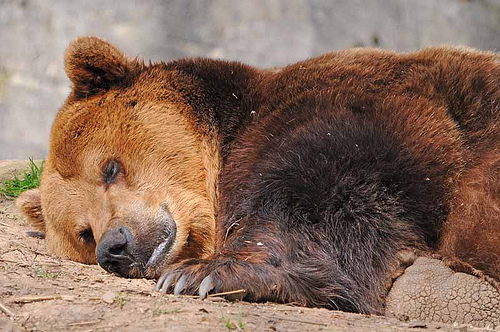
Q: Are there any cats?
A: No, there are no cats.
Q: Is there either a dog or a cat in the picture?
A: No, there are no cats or dogs.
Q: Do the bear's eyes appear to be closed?
A: Yes, the eyes are closed.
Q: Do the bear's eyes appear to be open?
A: No, the eyes are closed.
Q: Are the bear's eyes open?
A: No, the eyes are closed.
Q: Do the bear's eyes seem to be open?
A: No, the eyes are closed.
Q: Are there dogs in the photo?
A: No, there are no dogs.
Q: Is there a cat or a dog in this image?
A: No, there are no dogs or cats.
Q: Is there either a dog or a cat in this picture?
A: No, there are no dogs or cats.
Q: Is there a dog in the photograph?
A: No, there are no dogs.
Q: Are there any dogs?
A: No, there are no dogs.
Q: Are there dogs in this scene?
A: No, there are no dogs.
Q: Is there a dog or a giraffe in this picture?
A: No, there are no dogs or giraffes.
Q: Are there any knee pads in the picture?
A: No, there are no knee pads.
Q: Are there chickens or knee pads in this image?
A: No, there are no knee pads or chickens.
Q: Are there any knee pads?
A: No, there are no knee pads.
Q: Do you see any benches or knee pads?
A: No, there are no knee pads or benches.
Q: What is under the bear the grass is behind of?
A: The dirt is under the bear.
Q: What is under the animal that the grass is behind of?
A: The dirt is under the bear.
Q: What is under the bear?
A: The dirt is under the bear.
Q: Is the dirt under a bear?
A: Yes, the dirt is under a bear.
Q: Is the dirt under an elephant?
A: No, the dirt is under a bear.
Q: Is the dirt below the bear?
A: Yes, the dirt is below the bear.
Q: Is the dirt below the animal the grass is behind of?
A: Yes, the dirt is below the bear.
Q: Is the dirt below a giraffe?
A: No, the dirt is below the bear.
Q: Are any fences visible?
A: No, there are no fences.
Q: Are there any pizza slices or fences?
A: No, there are no fences or pizza slices.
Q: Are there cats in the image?
A: No, there are no cats.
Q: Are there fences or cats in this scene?
A: No, there are no cats or fences.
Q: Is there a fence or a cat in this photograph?
A: No, there are no cats or fences.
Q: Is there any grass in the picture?
A: Yes, there is grass.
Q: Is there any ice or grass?
A: Yes, there is grass.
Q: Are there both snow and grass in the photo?
A: No, there is grass but no snow.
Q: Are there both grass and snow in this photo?
A: No, there is grass but no snow.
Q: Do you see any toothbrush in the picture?
A: No, there are no toothbrushes.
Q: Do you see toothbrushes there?
A: No, there are no toothbrushes.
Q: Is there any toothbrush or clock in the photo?
A: No, there are no toothbrushes or clocks.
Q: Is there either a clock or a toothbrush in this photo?
A: No, there are no toothbrushes or clocks.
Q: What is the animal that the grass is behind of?
A: The animal is a bear.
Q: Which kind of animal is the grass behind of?
A: The grass is behind the bear.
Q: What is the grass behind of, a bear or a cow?
A: The grass is behind a bear.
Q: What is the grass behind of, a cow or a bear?
A: The grass is behind a bear.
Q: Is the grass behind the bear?
A: Yes, the grass is behind the bear.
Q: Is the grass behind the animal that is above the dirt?
A: Yes, the grass is behind the bear.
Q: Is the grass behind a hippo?
A: No, the grass is behind the bear.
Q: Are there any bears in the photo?
A: Yes, there is a bear.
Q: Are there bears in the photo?
A: Yes, there is a bear.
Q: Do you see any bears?
A: Yes, there is a bear.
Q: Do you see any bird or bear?
A: Yes, there is a bear.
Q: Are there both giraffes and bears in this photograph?
A: No, there is a bear but no giraffes.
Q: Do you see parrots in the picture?
A: No, there are no parrots.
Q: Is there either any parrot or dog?
A: No, there are no parrots or dogs.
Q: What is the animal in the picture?
A: The animal is a bear.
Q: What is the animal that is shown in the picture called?
A: The animal is a bear.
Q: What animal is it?
A: The animal is a bear.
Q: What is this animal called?
A: This is a bear.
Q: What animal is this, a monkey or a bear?
A: This is a bear.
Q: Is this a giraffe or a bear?
A: This is a bear.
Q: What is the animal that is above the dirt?
A: The animal is a bear.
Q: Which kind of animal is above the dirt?
A: The animal is a bear.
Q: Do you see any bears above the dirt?
A: Yes, there is a bear above the dirt.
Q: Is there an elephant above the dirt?
A: No, there is a bear above the dirt.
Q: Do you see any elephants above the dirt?
A: No, there is a bear above the dirt.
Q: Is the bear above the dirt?
A: Yes, the bear is above the dirt.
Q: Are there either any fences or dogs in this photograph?
A: No, there are no fences or dogs.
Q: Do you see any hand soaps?
A: No, there are no hand soaps.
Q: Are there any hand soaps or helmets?
A: No, there are no hand soaps or helmets.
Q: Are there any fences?
A: No, there are no fences.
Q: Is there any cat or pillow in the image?
A: No, there are no cats or pillows.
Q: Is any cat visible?
A: No, there are no cats.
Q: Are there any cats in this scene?
A: No, there are no cats.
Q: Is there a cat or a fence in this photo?
A: No, there are no cats or fences.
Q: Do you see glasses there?
A: No, there are no glasses.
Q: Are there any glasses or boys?
A: No, there are no glasses or boys.